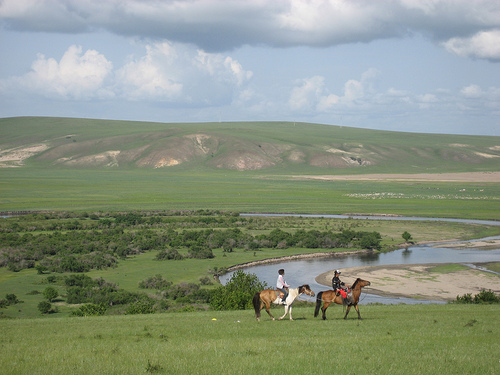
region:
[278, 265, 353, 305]
a body of water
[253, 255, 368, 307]
a body of calm water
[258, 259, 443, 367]
people riding horses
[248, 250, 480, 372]
people riding horses in a field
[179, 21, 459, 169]
a sky that is blue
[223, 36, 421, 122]
a sky with clouds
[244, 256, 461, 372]
two horses walking in a field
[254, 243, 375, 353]
two horses walking on the grass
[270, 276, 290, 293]
the arm of a persom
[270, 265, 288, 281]
the hair of a persom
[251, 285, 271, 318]
the tail of a horse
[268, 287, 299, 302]
the leg of a persom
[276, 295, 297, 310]
the foot of a persom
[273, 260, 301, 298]
the body of a persom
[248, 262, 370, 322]
Two cowboys wandering trail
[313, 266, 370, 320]
Man in red pants riding horse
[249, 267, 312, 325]
Man in white shirt riding horse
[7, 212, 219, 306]
Collection of thick trees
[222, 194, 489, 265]
Winding river surrounding by green landscape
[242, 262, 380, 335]
Two men on horses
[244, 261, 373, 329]
Two horses carrying modern dressed men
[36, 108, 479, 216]
Green field overshadowed by mountains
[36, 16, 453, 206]
Rolling clouds over mountain and green field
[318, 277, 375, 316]
the horse is brown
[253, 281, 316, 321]
the horse is brown and white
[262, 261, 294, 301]
the person is on the horse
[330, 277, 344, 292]
the top is black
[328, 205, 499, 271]
the river is curved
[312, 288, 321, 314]
the tail is black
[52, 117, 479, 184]
the hill is in the background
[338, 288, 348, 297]
the pants are red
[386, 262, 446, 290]
the ground is brown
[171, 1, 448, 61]
clouds are in the sky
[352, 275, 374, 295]
head of a horse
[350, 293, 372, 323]
leg of a horse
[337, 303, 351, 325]
leg of a horse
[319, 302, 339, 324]
leg of a horse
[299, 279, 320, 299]
head of a horse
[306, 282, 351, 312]
body of a horse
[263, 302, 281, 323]
leg of a horse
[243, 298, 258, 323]
tail of a horse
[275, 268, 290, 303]
the woman is riding a horse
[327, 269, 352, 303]
the man is riding a horse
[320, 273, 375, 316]
the horse is brown in color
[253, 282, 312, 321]
the horse is brown and white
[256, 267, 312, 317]
the rider is moving right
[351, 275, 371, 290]
the horse has his head raised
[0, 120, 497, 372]
the field is vast and green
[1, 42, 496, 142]
The cloudy sky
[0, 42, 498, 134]
A cloudy sky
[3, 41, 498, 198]
The mountain range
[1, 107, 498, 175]
A mountain range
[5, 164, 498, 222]
The flat area in the back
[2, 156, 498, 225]
A flat area near the mountain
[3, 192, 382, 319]
A forest of trees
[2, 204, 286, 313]
The forest of trees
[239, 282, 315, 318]
The horse to the left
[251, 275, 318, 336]
A horse to the left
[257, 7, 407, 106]
blue and white sky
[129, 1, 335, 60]
thick and puffy clouds